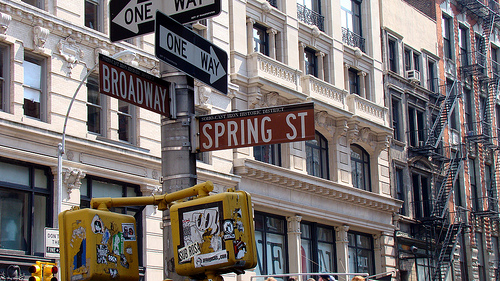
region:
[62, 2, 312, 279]
street signs in front of a building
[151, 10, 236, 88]
black and white one way sign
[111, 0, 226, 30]
black and white one way sign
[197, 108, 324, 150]
black, red, and white Spring St sign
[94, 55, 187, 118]
black, red, and white Broadway street sign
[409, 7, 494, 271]
black metal fire escape stairs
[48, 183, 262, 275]
yellow metal street lights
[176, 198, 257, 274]
stickers on yellow metal street light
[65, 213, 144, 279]
stickers on yellow metal street light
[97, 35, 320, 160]
intersection of Broadway and Spring St signs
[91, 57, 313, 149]
dark orange street signs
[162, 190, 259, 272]
pedestrian crossing signs with stickers on them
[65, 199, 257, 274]
variety of stickers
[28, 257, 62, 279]
pair of yellow street lights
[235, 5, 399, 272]
tall ornate stone building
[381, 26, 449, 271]
stack of windows on a building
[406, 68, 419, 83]
white air conditioner in a window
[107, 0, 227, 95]
black and white one way signs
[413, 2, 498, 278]
balconies and stairways up a building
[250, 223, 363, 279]
sign in the windows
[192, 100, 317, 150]
red and black sign with white lettering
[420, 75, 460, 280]
fire escape on a building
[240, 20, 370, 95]
a row of three windows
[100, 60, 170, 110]
the word "BROADWAY" in white letters on a red background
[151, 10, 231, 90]
a "one way" sign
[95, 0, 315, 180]
four signs attached to a pole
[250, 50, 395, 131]
three separate balconies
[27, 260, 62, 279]
a stoplight with the red light on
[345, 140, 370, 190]
a window with a rounded arch at the top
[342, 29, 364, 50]
a decorative black railing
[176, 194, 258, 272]
Stickers on a crosswalk sign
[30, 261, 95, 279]
Traffic light in the street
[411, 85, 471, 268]
fire escapes on a building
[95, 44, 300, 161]
street signs on a pole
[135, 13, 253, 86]
traffic signs showing one way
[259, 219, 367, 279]
Advertisement in the window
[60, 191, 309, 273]
stickers on a crosswalk sign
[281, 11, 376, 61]
Planters balcony on a building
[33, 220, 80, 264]
Traffic sign on a pole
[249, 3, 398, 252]
Brown building between two other buildings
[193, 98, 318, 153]
a red and white street sign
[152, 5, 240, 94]
a black and white one way sign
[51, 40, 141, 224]
a street light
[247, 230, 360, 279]
a white banner inside a building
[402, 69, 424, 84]
an airconditioner unit outside a window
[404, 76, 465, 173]
a fire escape on the outside of a building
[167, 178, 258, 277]
the back of a lighted walk/don't walk sign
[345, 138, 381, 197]
an arched window in a building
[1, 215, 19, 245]
a person visible though a window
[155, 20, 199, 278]
a metal pole holding street signs